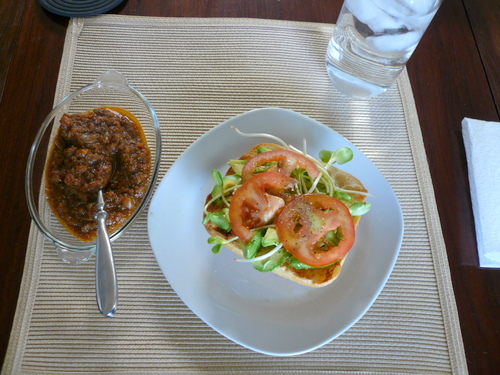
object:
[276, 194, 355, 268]
tomatoe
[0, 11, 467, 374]
tablecloth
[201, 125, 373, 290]
food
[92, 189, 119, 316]
handle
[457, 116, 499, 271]
blanket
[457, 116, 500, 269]
napkin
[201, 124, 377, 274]
vegetable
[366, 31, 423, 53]
ice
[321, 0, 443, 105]
water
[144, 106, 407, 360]
bowl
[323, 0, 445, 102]
glass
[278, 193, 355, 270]
tomatoes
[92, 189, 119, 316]
spoon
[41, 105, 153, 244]
food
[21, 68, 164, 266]
bowl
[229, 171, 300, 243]
tomato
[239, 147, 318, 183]
tomato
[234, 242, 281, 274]
greens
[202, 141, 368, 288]
bread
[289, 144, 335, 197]
sprouts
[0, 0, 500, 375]
table